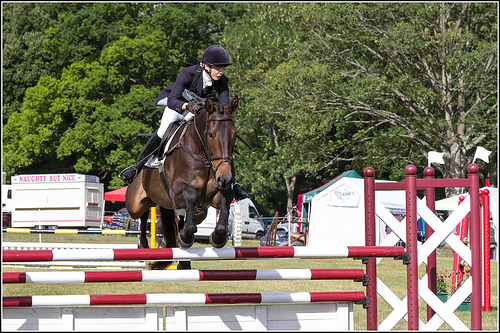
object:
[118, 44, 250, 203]
woman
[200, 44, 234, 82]
black hat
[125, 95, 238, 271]
horse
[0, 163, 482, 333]
fence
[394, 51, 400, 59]
leaves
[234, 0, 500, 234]
trees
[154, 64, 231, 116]
black jacket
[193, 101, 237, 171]
harness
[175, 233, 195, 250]
hooves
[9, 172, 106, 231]
snack bar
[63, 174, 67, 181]
letters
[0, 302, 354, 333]
base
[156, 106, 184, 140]
pants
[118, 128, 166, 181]
boots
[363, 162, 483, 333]
scaffolding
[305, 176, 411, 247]
tents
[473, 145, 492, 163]
flag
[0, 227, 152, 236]
pole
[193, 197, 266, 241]
van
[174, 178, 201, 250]
legs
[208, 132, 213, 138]
eyes